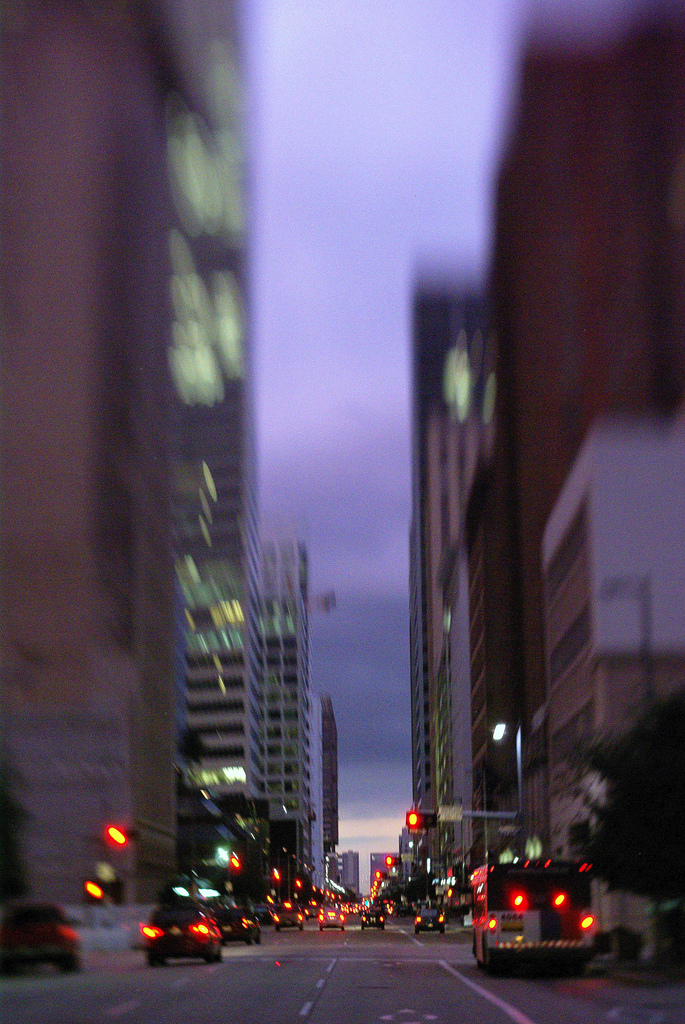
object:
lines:
[299, 958, 336, 1021]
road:
[0, 896, 685, 1024]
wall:
[0, 110, 104, 422]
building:
[0, 0, 263, 911]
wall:
[0, 0, 144, 662]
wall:
[242, 621, 311, 793]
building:
[244, 536, 323, 876]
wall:
[515, 235, 685, 471]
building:
[408, 0, 685, 863]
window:
[249, 769, 283, 793]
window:
[266, 725, 297, 775]